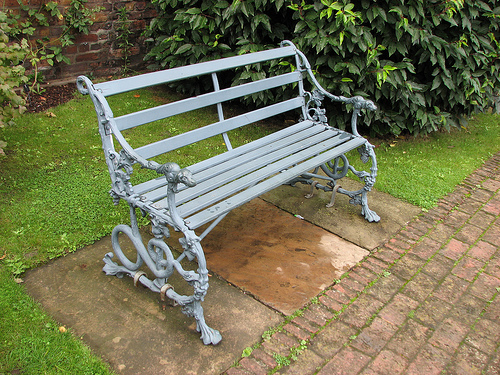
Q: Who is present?
A: No one.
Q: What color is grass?
A: Green.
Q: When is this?
A: Daytime.